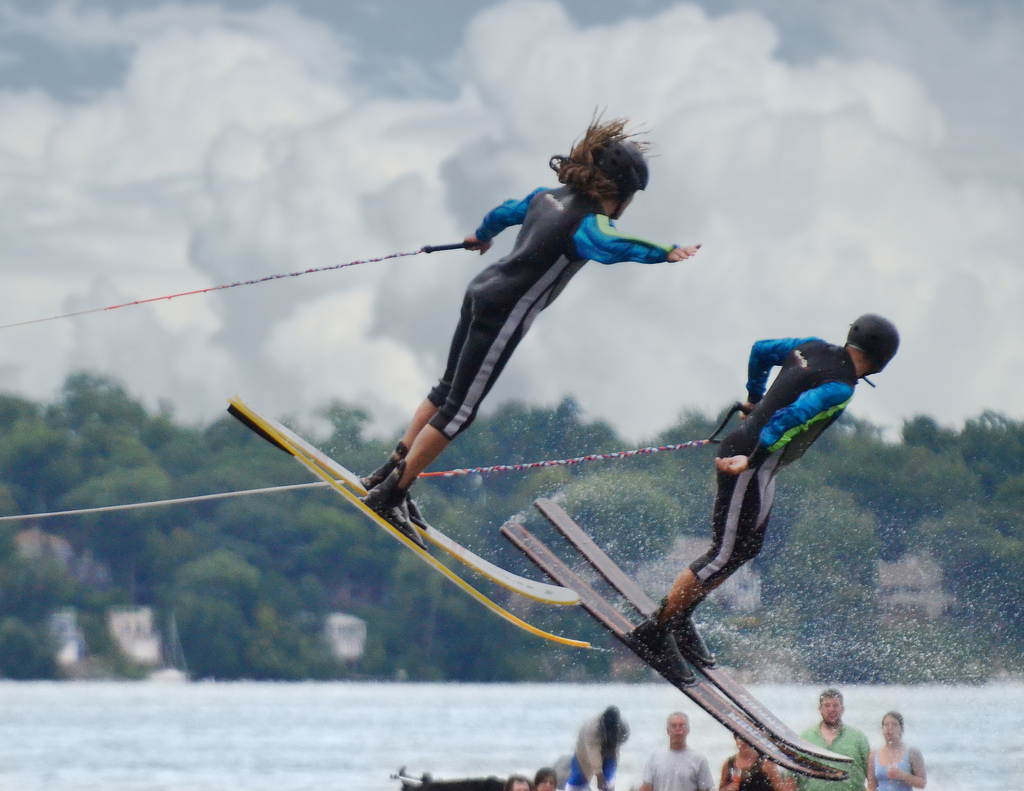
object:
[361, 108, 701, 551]
people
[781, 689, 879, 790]
man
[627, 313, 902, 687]
man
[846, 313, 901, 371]
helmets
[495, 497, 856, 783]
skiis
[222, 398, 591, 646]
skiis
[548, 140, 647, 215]
helmets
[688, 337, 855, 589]
wet suits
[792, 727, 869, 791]
shirt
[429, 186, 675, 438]
wet suit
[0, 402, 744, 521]
rope